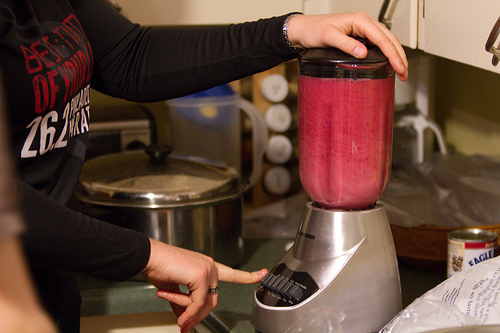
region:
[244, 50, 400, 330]
silver and black blender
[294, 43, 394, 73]
black lid of the blender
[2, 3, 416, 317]
person using the blender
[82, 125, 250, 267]
silver pot with lid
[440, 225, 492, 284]
can on the counter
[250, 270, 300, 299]
black buttons on the blender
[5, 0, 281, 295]
black shirt blender user is wearing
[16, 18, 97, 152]
red and white lettering on the shirt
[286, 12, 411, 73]
hand on top of the blender lid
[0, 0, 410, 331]
A woman is using the blender.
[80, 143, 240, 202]
A metal lid with a black plastic knob.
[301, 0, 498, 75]
Cabinet doors with handles pointed diagonally.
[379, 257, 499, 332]
A plastic bag with writing on it.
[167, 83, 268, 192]
A plastic jug with a blue lid in it.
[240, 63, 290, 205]
A wooden spice rack.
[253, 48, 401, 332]
A blender with a pink liquid in the container.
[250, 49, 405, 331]
a silver colored blender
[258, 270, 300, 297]
a line of black buttons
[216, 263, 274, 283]
a finger pushing a black button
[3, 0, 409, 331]
the person has a watch on their left arm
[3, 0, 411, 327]
a person wearing a black colored shirt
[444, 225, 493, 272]
a can of sweetened condensed milk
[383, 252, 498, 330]
a white paper with a recipe on it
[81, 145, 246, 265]
a round silver pot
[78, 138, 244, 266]
the silver pot has a lid on top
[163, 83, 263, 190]
an empty clear plastic jug in the background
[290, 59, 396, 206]
The liquid inside the blender is red.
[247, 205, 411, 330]
The bottom of the blender is black and silver.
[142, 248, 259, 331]
The woman is wearing a ring.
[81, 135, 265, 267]
The pot is silver.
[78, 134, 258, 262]
The pot is made of metal.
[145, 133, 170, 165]
The pot knob is black.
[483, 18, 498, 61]
The kitchen cabinet knob is silver and brown.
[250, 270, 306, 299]
The blender buttons are grey.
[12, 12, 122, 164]
The woman's shirt has red and white writing.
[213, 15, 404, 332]
person operation a blender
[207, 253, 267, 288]
person finger on the button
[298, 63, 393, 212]
red liquid in the blender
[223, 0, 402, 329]
silver and black blender on the counter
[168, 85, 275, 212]
Pitcher on the counter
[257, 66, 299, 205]
seasoning rack on the counter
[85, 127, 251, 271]
silver pot on the stove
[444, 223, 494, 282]
can on the counter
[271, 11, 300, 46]
woman wearing a bracelet